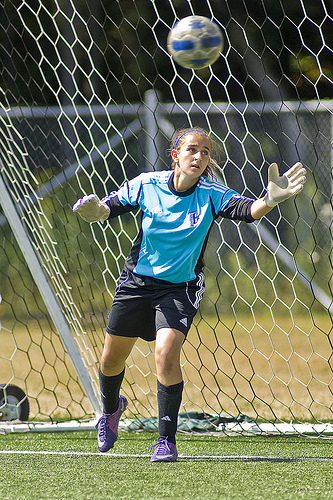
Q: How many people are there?
A: One.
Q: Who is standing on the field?
A: A woman.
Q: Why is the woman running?
A: She is trying to hit the ball.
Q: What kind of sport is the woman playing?
A: Soccer.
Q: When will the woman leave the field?
A: After she has finished playing soccer.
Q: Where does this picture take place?
A: On a soccer field.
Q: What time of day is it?
A: Daytime.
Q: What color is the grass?
A: Green.